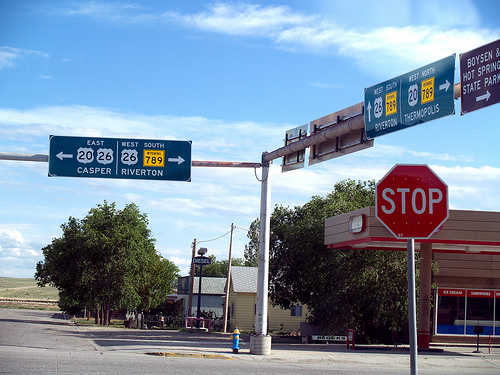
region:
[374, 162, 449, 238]
A stop sign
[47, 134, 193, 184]
A traffic sign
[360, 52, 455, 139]
A traffic sign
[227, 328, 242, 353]
A blue and yellow fire hydrant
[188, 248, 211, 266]
A gas station sign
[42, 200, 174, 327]
Several trees on the side of the road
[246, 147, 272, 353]
A pole holding the traffic signs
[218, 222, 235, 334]
A telephone poll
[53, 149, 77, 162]
A left pointing arrow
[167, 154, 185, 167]
A right pointing arrow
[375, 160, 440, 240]
red Stop sign in foreground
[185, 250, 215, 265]
Diesel sign with white lettering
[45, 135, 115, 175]
Eastbound sign to Casper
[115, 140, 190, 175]
West and southbound sign Riverton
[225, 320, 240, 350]
blue hydrant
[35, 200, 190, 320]
large tree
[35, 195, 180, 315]
large green tree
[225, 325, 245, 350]
fire hydrant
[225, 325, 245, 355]
blue and yellow fire hydrant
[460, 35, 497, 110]
Boysen and Hot Springs state park sign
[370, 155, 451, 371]
a red stop sign at an intersection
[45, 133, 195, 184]
directional signs are above the street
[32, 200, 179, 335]
Trees are near the intersection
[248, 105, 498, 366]
a store is on the corner of the intersection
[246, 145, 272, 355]
a pole is holding up the directional signs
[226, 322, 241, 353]
a fire hydrant is at the intersection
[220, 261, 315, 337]
a yellow house is near the intersection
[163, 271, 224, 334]
a blue house is near the intersection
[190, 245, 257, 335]
a pole with a sign is in front of a house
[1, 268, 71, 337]
a hill is in the background of the intersection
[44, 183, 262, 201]
blue sky with pale white clouds.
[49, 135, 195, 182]
a green street sign with many numbers and words on it.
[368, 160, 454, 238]
red and white stop sign.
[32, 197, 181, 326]
A large green tree near the road.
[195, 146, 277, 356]
A street sign pole near a fire hydrant, in front of houses.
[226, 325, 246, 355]
a blue and yellow fire hydrant.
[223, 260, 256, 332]
an off-white house near the road.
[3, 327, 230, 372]
part of a gray concrete road.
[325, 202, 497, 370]
A brown and red store behind a stop sign.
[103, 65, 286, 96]
a part of sky that is only blue, and cloudless.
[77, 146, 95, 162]
The number 20 on a sign.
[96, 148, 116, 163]
The number "26" on a sign.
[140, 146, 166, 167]
Sign with numbers "789" on it.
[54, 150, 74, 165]
A white arrow turning left.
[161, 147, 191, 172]
A white arrow turning right.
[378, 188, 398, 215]
The white letter "S" on a sign.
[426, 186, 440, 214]
White letter "P" on a sign.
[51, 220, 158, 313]
A large green tree.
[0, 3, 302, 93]
A clear blue sky with clouds.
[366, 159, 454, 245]
A readable stop sign in the street.